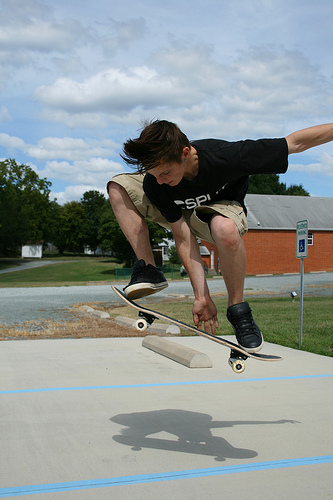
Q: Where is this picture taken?
A: Parking lot.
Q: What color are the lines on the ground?
A: Blue.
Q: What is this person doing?
A: Skateboarding.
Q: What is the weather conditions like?
A: Partly cloudy.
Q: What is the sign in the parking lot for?
A: Handicap parking spot.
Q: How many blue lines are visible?
A: Two.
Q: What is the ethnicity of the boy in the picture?
A: Caucasian.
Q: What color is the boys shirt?
A: Black.